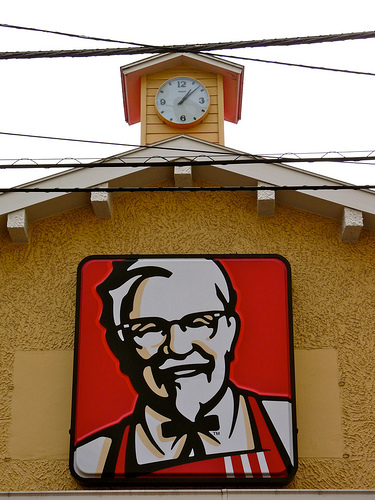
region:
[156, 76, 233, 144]
the clock shows 1:08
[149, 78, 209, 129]
the clock shows 1:08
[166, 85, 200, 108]
clock's hands are black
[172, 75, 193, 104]
clock's hands are black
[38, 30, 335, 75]
a rode is on top of he buildig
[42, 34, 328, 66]
the rode is wooden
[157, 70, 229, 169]
a clock is on top roof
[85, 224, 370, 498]
a picture frame is on the wall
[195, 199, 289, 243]
wall ois brwon in color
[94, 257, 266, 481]
the picutre is sketchy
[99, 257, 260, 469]
the picture is ofa man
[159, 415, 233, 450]
the sketch has a neck tie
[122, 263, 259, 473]
the frame is red in color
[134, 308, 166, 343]
eye of a comic person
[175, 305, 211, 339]
eye of a comic person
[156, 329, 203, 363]
nose of a comic person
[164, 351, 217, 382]
mouth of a comic person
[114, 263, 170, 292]
hair of a comic person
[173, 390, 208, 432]
beard of a comic person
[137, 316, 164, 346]
an eye of a comic person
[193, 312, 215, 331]
an eye of a comic person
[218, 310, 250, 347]
an ear of a comic person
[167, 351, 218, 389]
a mouth of a comic person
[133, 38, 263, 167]
a white and black clock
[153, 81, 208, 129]
the face of a clock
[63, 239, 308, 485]
a large Kentucky Fried Chicken sign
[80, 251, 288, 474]
a man wearing glasses and an apron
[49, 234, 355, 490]
a large sign on a wall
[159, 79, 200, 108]
the black hands of a clock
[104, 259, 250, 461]
a man wearing a bow tie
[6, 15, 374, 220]
wires hanging over a building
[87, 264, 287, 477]
col sanders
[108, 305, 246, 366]
black glasses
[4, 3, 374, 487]
the front of KFC restaurante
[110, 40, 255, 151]
a clock tower on a KFC restaurant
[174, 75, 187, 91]
the 12 on a clock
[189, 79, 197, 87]
the number 1 on a clock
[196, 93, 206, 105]
the 3 on a clock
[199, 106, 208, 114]
the number 4 on a clock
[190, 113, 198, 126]
the number 5 on a clock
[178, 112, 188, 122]
the number 6 on a clock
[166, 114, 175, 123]
the number 7 on a clock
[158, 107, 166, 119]
the number 8 on a clock